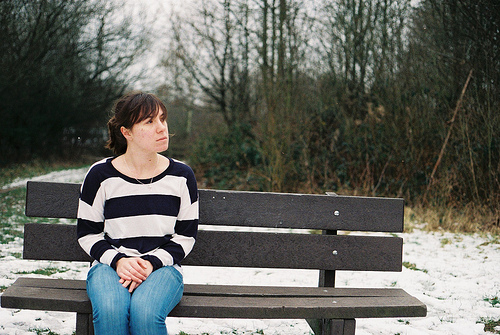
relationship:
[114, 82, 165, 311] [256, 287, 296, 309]
woman on bench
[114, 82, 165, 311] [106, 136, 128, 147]
woman has ponytail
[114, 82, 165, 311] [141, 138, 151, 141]
woman hs pimples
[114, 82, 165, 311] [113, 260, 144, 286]
woman holding hands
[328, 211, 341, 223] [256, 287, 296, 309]
bolts on bench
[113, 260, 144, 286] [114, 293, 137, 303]
hands in lap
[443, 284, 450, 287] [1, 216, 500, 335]
snow on field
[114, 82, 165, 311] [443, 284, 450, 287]
woman in snow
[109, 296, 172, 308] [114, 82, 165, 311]
jeans on woman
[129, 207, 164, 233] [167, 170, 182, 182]
stripes on shirt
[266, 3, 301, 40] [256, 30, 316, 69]
branch on trees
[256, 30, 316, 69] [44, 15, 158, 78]
trees in woods